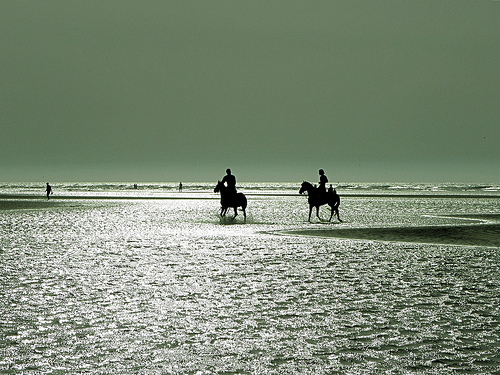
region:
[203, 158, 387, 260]
two people on horses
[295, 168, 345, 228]
black silhouette of a person on a horse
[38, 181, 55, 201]
person walking along the beach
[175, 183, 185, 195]
very tiny person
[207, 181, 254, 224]
horse running through the water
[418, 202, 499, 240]
wave rolling in over the sand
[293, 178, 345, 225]
horse walking through the shallow water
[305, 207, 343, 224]
the outline of four horse legs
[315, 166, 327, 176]
tiny human head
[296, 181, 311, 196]
silhouette of a horse head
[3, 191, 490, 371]
the beach with a bunch of wet sand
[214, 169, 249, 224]
a person riding the horse on the beach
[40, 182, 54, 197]
a person walking on the beach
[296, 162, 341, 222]
another person riding a horse on the beach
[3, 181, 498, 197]
the ocean next to the beach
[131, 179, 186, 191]
a couple of people on the beach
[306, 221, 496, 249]
a dry part of the beach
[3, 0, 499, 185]
the sky above the beach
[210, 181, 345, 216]
a couple of horses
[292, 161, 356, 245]
A horse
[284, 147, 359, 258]
A horse walking on a beach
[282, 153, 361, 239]
A person riding a horse on a beach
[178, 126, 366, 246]
Two horses walking on a beach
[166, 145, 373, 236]
two horses with riders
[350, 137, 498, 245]
The horizon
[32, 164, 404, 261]
A beach with people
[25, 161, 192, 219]
People in the water at a beach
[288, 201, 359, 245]
The legs of a horse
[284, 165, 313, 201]
The head of a horse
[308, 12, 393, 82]
part of the sky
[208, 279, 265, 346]
part of a water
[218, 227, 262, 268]
part of some waves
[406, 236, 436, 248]
edge of a lagoon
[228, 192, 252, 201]
part of a horse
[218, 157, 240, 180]
part of a head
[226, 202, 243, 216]
part of a knee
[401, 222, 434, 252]
part of some sand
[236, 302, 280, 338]
part of a water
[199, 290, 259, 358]
part of some waves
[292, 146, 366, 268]
A horse on a beach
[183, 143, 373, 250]
two horses on a beach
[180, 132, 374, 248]
two people riding horses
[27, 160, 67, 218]
A person on a beach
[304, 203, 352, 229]
The legs of a horse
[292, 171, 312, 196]
The head of a horse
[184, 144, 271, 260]
A horse running in the ocean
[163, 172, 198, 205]
A person in the waves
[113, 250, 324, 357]
water